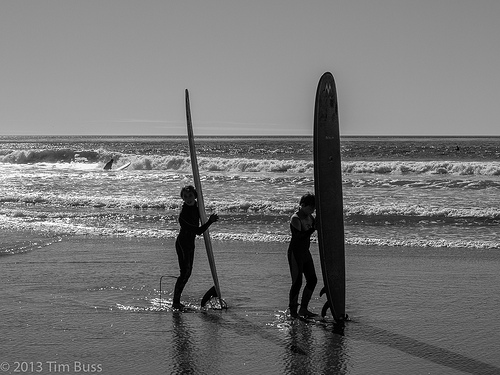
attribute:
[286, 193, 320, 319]
lady — standing, girl, female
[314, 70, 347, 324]
surfboard — black, long, upright, tall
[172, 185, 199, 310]
girl — standing, surfing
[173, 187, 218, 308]
girl — young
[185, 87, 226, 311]
surfboard — white, light colored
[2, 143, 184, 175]
waves — rolling, breaking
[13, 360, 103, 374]
letters — grey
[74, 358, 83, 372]
letter — grey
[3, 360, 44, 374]
numbers — grey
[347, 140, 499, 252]
waves — breaking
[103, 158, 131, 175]
surfer — surfing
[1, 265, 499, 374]
water — receeding